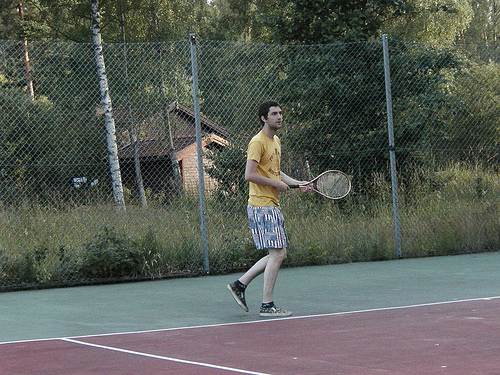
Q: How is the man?
A: In motion.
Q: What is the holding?
A: A racket.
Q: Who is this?
A: A man.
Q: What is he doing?
A: Playing.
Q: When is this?
A: Daytime.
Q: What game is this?
A: Tennis.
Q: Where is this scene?
A: At a tennis court.